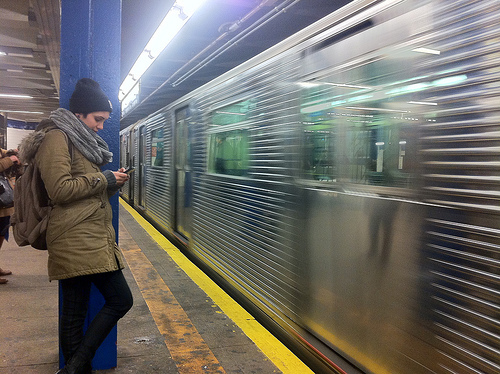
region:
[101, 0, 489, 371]
blurr of a train in motion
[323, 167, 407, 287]
legs of waiting passenger reflected in door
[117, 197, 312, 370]
yellow caution lines painted on the platform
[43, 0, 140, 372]
a blue support beam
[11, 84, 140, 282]
young girl uses cell phone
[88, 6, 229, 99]
overhead fluorescent lighting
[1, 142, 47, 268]
backpack is packed full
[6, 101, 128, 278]
grey scarf with khaki coat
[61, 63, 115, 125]
a black knitted hat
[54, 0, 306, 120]
pipes showing over tracks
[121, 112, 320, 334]
the train is silver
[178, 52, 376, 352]
the train is silver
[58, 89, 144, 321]
a woman looking at her phone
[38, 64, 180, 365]
a woman looking at her phone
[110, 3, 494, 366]
blurred train in motion next to train platform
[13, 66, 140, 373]
person leaning on blue pole on train platform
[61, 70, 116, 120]
black knit hat on person standing on train platform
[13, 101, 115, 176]
grey scarf around neck of person on train platform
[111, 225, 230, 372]
yellow worn line on train platform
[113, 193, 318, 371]
yellow painted curb of train platform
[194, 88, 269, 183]
blurred window on side of train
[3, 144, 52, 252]
tan book bag on back of person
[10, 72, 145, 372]
person on train platform looking at cell phone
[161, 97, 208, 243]
doors on side of train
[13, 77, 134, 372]
Woman texting on phone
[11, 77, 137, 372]
Woman waiting for train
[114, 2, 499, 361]
Train moving by fast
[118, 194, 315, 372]
Yellow line indicating not to cross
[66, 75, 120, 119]
A black womans hat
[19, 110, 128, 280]
A woman in coat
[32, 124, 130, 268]
A borwn winter coat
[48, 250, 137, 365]
Black womans leggings long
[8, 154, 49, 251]
A back pack for women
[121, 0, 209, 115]
Lights hangning in station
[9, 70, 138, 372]
Person looking at a cell phone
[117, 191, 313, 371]
Yellow paint on the platform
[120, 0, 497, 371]
Silver train in motion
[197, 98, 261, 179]
Window on the train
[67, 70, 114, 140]
Black hat on person's head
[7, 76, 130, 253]
Person is carrying a bag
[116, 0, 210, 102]
Lights on the ceiling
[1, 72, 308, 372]
Person standing on a train platform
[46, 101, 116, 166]
Scarf around person's neck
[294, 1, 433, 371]
Doors of a train